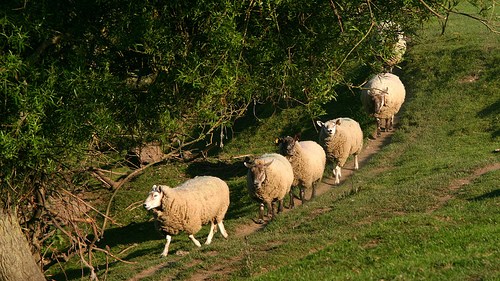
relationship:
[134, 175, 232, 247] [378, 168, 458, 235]
sheep walking in grass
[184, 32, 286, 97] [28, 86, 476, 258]
leaves covering sheep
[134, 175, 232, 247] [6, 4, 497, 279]
sheep walking in grass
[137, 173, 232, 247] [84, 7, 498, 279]
sheep in grass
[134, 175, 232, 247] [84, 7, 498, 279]
sheep on grass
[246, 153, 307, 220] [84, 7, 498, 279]
sheep on grass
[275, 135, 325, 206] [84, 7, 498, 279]
sheep on grass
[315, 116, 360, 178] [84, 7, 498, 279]
sheep on grass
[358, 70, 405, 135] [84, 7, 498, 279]
sheep on grass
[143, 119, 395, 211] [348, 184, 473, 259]
sheep in grass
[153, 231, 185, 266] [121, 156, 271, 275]
leg on sheep